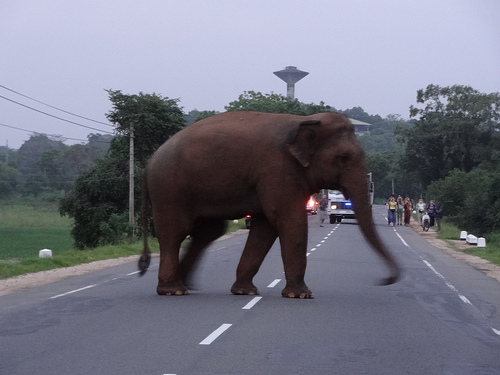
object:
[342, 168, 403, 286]
truck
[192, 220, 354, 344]
lines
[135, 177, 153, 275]
tail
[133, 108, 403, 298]
elephant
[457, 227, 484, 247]
objects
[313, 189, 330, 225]
man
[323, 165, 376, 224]
rv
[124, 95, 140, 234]
pole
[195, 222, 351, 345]
stripes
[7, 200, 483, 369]
pavement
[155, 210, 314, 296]
legs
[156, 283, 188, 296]
feet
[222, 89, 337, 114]
tops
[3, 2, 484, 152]
sky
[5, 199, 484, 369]
street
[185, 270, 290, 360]
lines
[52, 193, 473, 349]
street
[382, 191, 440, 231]
people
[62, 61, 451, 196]
background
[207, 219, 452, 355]
street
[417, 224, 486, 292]
side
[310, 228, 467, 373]
road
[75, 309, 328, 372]
pavement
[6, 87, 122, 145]
lines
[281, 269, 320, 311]
foot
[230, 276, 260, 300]
foot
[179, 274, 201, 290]
foot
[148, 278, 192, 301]
foot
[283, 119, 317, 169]
ear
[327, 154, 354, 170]
eye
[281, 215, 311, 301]
leg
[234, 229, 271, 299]
leg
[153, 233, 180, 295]
leg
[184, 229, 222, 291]
leg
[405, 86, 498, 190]
tree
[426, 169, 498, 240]
tree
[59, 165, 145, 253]
tree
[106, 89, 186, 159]
tree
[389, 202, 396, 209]
shirt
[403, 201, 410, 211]
shirt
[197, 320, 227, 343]
line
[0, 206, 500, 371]
road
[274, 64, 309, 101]
building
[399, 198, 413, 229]
person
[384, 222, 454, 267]
road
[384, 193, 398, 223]
person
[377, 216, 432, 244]
street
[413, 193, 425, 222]
person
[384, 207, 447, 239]
street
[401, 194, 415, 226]
person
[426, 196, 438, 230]
person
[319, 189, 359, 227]
car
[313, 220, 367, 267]
street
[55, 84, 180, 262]
tree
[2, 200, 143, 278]
field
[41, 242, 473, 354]
street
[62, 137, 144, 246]
trees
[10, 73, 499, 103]
background